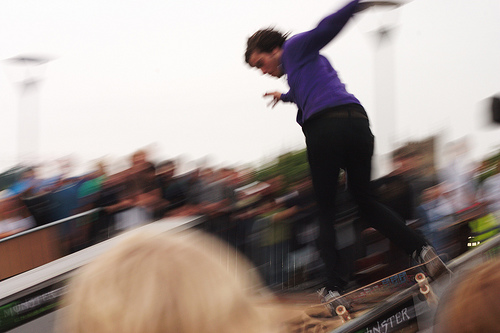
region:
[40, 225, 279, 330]
A blonde person.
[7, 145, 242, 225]
People in the crowd watching.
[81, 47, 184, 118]
The sky is white.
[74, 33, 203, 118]
The sky is bright.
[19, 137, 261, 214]
The background is blurry.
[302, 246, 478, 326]
A skateboard.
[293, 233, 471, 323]
The wheels are white.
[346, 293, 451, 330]
A logo under the skateboard.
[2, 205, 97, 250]
A hand rail is seen.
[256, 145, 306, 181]
Trees in the background.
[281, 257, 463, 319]
a blurry skate board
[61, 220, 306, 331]
top of woman's head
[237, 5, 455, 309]
a skate boarder going fast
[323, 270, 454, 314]
red and white wheels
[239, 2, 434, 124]
skate boarder in purple shirt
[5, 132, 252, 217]
a crowd of onlookers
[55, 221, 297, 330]
woman's blonde hair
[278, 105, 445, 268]
pair of black jeans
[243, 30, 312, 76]
man with brown hair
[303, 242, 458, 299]
skateboarder with black and white sneakers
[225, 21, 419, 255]
guy in purple shirt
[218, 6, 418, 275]
man wearing skinny pants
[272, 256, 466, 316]
skate board going down ramp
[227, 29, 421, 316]
guy riding skate board on a ramp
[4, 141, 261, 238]
blurry spectators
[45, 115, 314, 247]
people watching skateboarder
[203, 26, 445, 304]
guy on a skateboard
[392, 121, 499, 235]
blurry people watching man skateboarding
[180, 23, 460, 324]
man doing tricks on a skateboard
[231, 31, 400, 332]
man wearing purple on a skateboard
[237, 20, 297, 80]
the head of a person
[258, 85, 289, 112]
the hand of a person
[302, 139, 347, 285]
the leg of a person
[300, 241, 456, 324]
a black skateboard under the person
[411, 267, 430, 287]
a white skateboard wheel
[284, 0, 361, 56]
the arm of a person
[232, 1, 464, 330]
a person on a skateboard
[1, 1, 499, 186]
a gray sky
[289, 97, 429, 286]
a pair of black pants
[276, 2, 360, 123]
a purple shirt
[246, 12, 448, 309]
Man skateboarding on a rail.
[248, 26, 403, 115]
Man with purple shirt.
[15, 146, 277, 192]
People watching skateboarder.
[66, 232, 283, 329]
Blonde haired person up close.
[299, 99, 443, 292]
Man with black colored pants.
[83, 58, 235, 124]
White colored clear sky.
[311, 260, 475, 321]
Black and blue colored skateboard.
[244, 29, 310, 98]
Man with brown colored hair.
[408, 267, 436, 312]
White and red colored wheels.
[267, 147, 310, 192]
Green colored tree in background.